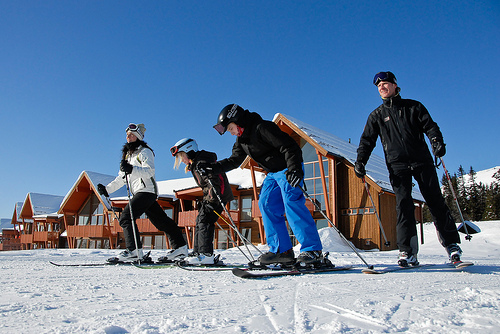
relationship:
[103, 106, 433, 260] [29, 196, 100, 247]
family at ski lodge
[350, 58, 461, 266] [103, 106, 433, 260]
father of family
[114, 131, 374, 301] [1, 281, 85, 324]
skiers on slopes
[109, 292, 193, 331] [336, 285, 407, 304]
tracks on snow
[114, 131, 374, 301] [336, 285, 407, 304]
skiers on snow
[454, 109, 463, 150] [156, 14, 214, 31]
clouds in sky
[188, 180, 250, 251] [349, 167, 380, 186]
ski pole in hand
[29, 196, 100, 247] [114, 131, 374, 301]
ski lodge behind skiers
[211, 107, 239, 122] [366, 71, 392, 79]
helmet attached to goggles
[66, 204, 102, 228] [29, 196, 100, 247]
balcony of ski lodge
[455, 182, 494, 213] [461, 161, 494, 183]
trees in background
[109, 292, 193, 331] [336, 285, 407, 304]
tracks in snow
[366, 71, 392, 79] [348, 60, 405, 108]
goggles on head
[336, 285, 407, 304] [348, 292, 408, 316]
snow on ground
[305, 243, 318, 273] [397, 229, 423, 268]
boot on foot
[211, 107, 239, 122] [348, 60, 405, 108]
helmet on head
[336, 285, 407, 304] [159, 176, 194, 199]
snow on roof